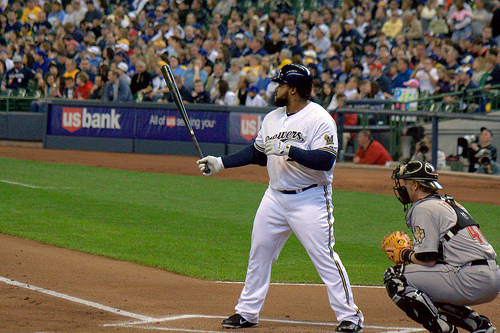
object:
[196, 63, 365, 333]
batter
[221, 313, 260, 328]
cleats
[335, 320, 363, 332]
cleats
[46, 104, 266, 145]
banner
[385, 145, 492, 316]
train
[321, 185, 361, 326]
stripe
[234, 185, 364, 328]
pants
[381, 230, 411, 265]
mitt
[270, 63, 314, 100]
helmet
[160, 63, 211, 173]
bat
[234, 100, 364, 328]
uniform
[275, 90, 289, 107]
black beard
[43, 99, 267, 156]
ads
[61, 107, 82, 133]
shield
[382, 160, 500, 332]
catcher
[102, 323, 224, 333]
lines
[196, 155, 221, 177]
gloves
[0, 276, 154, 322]
base line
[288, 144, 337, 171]
sleeve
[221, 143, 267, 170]
sleeve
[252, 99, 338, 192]
shirt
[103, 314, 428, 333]
home plate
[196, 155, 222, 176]
right hand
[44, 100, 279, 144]
tarp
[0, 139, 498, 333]
field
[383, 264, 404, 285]
knee guard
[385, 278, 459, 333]
leg guard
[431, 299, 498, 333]
leg guard